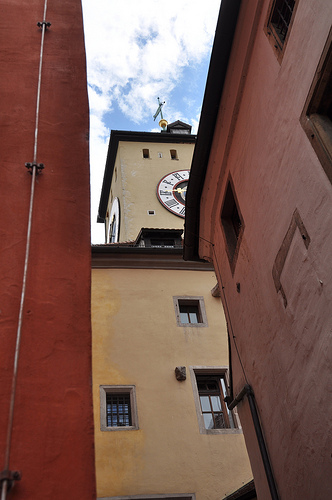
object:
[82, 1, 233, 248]
cloud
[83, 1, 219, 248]
sky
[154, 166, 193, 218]
clock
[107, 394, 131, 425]
bars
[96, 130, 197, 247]
tower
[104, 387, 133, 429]
windows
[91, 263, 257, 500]
building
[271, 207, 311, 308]
window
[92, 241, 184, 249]
tiles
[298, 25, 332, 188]
door frame